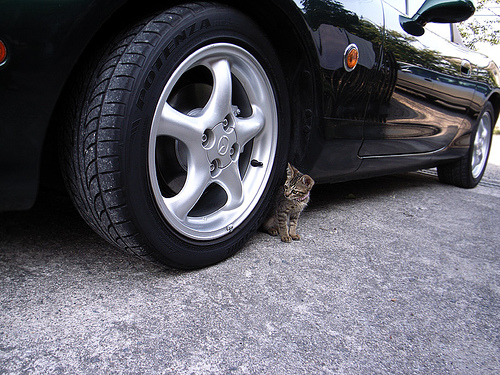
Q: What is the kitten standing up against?
A: A new, clean tire.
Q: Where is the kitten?
A: Hiding behind a wheel.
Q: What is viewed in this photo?
A: Two tires and one cat.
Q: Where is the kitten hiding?
A: The front driver side wheel of a black car.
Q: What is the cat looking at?
A: Tire.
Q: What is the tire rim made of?
A: Chrome.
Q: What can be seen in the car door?
A: Reflection.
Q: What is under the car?
A: Cat.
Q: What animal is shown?
A: Cat.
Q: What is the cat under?
A: Car.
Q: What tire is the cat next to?
A: Left front tire.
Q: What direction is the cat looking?
A: Left.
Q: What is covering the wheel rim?
A: Hubcap.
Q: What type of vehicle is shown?
A: A sports car.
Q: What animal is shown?
A: A cat.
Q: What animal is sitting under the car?
A: A cat.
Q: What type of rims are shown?
A: Aluminum.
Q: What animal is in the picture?
A: Kitten.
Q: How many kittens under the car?
A: One.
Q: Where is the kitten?
A: Under the car.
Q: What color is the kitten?
A: Black and gray.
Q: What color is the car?
A: Black.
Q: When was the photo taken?
A: Daytime.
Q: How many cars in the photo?
A: One.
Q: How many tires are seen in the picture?
A: Two.